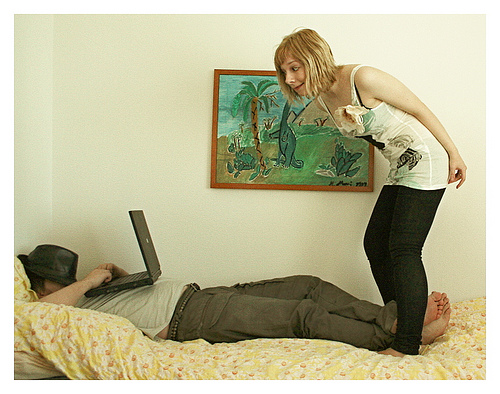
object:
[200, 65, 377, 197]
picture frame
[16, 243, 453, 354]
man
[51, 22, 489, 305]
room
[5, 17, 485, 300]
white wall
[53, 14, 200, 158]
part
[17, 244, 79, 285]
hat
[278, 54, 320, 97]
face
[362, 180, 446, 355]
black jeans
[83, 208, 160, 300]
laptop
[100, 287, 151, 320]
stomach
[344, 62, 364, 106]
strap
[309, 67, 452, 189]
shirt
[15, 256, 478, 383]
bedspread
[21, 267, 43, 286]
hair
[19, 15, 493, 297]
wall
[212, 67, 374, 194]
painting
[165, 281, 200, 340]
belt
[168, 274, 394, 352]
pants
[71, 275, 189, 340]
shirt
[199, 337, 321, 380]
flowers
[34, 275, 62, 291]
face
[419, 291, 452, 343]
feet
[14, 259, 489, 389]
bed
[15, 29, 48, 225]
wall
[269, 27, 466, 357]
woman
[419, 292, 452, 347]
feet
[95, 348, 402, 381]
print